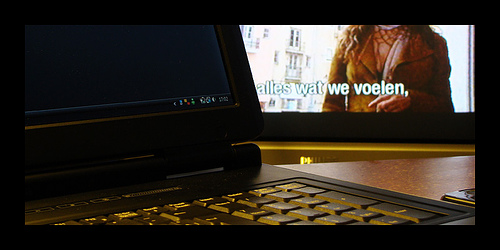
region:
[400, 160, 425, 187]
part of a table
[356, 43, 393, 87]
part of a screen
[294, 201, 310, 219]
part of a button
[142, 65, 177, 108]
part of a screen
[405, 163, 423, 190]
part of a table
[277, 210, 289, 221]
part of a button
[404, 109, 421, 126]
edge of a screen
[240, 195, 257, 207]
part of a button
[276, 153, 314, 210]
part of a board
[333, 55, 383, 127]
part of a screen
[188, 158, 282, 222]
the keyboard is black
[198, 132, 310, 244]
the keyboard is black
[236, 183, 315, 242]
the keyboard is black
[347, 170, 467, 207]
the countertop is brown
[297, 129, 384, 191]
the countertop is brown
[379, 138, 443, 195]
the countertop is brown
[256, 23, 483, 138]
closed captioning on a television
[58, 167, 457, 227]
black keyboard to a comoputer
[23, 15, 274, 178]
black screen on a computer monitor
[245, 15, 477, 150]
television set that is on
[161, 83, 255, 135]
colorful icons on a computer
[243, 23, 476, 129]
movie with a women infront of a building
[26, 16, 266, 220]
computer screen that is black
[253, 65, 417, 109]
closed captioning for a tv show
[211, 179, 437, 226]
number keypad for computer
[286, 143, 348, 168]
name plate for television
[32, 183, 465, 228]
black lap top keyboard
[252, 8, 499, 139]
television on in the background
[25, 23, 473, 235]
black lap top open on table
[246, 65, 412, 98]
white lettering on tv screen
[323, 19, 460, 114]
woman with brown jacket on tv screen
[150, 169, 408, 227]
light from tv shining on lap top keyboard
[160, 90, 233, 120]
icons on computer screen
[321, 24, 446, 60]
woman with long brown hair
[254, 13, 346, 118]
buildings on the tv screen in the background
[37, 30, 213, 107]
computer screen is solid black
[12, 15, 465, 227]
a laptoon on a desk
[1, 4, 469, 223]
laptop is color black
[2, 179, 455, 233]
keyboard is black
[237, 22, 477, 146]
a TV behind a screen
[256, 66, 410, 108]
white words on a screen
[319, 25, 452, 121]
woman with long hair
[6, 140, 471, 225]
laptop on brown table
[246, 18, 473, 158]
TV over a yellow surface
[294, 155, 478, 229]
a book near a lapto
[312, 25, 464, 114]
woman wears a green jacket